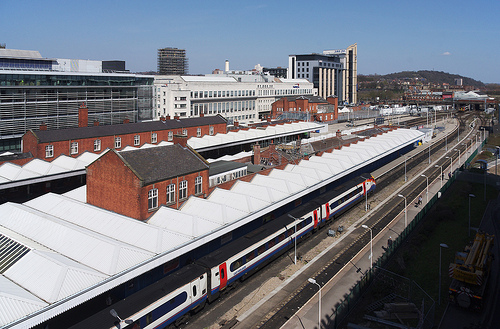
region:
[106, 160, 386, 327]
the train is white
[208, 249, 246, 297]
red door on the train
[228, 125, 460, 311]
white line on platforn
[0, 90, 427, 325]
this is a train station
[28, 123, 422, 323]
white roof of station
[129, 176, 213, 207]
windows on the station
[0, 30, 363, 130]
building in the background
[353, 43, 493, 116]
land mass in the background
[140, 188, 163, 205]
a window on a building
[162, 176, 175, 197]
a window on a building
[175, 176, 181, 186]
a window on a building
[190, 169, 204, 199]
a window on a building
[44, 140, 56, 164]
a window on a building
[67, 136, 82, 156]
a window on a building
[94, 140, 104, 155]
a window on a building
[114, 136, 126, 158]
a window on a building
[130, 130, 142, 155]
a window on a building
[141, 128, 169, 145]
a window on a building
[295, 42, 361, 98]
A large distant building colored beige and gray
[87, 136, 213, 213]
A small brick building with an angular roof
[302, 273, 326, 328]
A tall white street light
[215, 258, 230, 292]
A tall thin train door painted red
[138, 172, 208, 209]
Four white windows on a brick wall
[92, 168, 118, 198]
A brick wall section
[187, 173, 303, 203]
A series of triangular roofs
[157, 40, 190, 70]
A round gray building against a blue sky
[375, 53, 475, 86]
A slightly sloped mountain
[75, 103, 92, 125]
A red thick chimney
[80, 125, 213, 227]
red brick building with black roof near train tracks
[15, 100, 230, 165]
long red brick building with black roof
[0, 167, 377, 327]
red white blue and black train stopped at train station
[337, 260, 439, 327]
light gray metal chain-link fence near train tracks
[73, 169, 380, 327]
train in train station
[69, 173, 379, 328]
train on railway tracks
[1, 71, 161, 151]
building in distance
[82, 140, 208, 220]
building has four windows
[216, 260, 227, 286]
red door on train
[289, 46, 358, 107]
building in distance